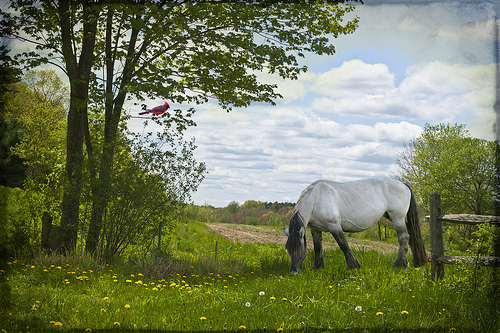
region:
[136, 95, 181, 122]
red bird in a tree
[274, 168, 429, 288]
horse standing in the grass by the road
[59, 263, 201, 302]
little yellow flowers in the grass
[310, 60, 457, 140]
white clouds in the blue sky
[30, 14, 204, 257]
tree with a bird on it's branch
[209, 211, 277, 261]
dirt road behind the horse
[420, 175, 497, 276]
wooden fence beside the road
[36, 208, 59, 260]
tree stump behind the flowers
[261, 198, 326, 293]
horse eating grass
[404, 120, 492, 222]
tree across the road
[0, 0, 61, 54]
white clouds against blue sky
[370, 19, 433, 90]
white clouds against blue sky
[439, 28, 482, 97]
white clouds against blue sky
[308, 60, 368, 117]
white clouds against blue sky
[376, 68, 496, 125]
white clouds against blue sky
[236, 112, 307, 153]
white clouds against blue sky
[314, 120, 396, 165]
white clouds against blue sky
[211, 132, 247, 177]
white clouds against blue sky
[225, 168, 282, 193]
white clouds against blue sky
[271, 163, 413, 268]
gray and black horse grazing on grass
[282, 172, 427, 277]
gray horse with black mane and tail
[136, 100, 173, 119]
red cardinal bird on a tree branch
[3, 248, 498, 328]
yellow and white flowers in a field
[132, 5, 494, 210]
puffy clouds in a blue sky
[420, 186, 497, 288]
section of a fence post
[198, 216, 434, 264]
a dirt road in the country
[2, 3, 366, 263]
two trees with leaves side-by-side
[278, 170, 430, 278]
horse eating grass in a field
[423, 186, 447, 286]
end post of a fence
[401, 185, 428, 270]
long, black tail of a horse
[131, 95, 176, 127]
a red bird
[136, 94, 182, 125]
a bird perched on a branch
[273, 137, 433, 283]
a white and gray horse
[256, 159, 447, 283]
a horse eating grasss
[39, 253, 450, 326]
a patch of grass full of dandelions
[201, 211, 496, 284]
a dirt road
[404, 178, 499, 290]
a wooden post fence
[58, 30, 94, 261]
a tree with a thin trunk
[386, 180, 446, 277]
a long horses tail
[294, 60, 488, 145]
white fluffy clouds in the sky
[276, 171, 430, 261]
gray horse grazing on green grass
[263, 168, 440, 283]
black and gray horse grazing on green grass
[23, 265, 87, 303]
green grass with yellow flowers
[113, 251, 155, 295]
green grass with yellow flowersgreen grass with yellow flowers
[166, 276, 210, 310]
green grass with yellow flowers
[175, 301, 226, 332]
green grass with yellow flowers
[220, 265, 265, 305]
green grass with yellow flowers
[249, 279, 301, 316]
green grass with yellow flowers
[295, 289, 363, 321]
green grass with yellow flowers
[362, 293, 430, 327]
green grass with yellow flowers